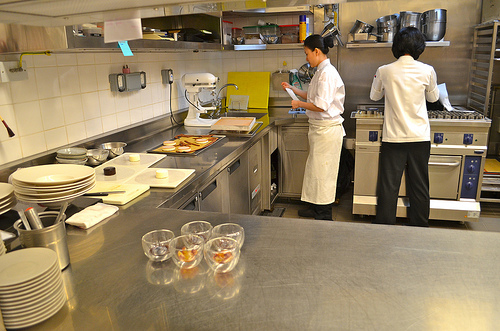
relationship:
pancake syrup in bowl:
[141, 218, 253, 278] [168, 235, 204, 269]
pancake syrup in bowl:
[141, 218, 253, 278] [204, 237, 245, 273]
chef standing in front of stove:
[370, 26, 440, 227] [331, 59, 498, 247]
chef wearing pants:
[370, 26, 440, 227] [376, 142, 432, 229]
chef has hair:
[281, 34, 347, 221] [301, 27, 336, 49]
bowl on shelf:
[420, 7, 448, 19] [343, 35, 453, 50]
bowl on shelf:
[419, 23, 448, 40] [343, 35, 453, 50]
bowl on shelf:
[378, 27, 398, 42] [343, 35, 453, 50]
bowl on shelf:
[375, 14, 401, 25] [343, 35, 453, 50]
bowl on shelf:
[356, 18, 372, 33] [343, 35, 453, 50]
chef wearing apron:
[278, 22, 354, 224] [300, 117, 343, 204]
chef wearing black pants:
[370, 25, 439, 227] [375, 140, 430, 226]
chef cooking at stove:
[370, 25, 439, 227] [348, 101, 492, 225]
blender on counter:
[182, 73, 219, 127] [146, 104, 254, 149]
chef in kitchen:
[370, 26, 440, 227] [0, 2, 498, 329]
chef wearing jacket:
[370, 26, 440, 227] [369, 56, 440, 144]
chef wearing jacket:
[370, 26, 440, 227] [372, 63, 469, 148]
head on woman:
[297, 30, 334, 72] [273, 26, 362, 222]